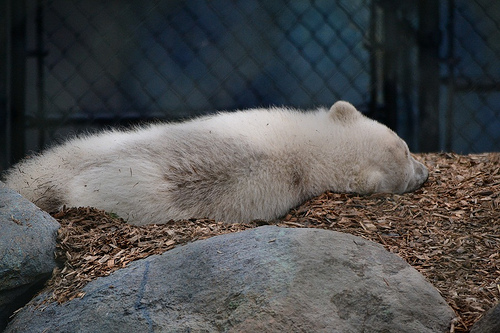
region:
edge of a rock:
[368, 255, 387, 280]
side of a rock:
[173, 287, 185, 294]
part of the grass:
[456, 231, 476, 257]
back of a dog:
[131, 135, 166, 186]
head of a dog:
[386, 148, 391, 158]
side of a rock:
[56, 250, 62, 260]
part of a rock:
[188, 278, 201, 291]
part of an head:
[374, 153, 393, 174]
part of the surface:
[444, 193, 456, 215]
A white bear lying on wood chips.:
[0, 100, 488, 227]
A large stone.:
[5, 225, 460, 330]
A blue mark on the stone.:
[121, 257, 161, 327]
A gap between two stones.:
[3, 275, 55, 326]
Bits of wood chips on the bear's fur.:
[7, 116, 328, 211]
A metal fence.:
[5, 15, 495, 155]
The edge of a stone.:
[470, 300, 495, 330]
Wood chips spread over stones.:
[0, 151, 495, 328]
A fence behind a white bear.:
[7, 22, 492, 219]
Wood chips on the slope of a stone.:
[21, 278, 86, 310]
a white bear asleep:
[30, 100, 446, 232]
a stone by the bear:
[35, 220, 470, 327]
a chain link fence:
[50, 13, 404, 122]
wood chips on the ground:
[377, 185, 469, 250]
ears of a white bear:
[309, 100, 394, 199]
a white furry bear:
[49, 103, 429, 223]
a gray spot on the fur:
[139, 125, 251, 211]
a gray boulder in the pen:
[157, 201, 449, 326]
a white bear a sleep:
[60, 91, 460, 236]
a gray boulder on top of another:
[10, 164, 117, 331]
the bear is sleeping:
[101, 92, 447, 229]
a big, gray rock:
[175, 200, 296, 303]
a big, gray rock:
[249, 214, 436, 329]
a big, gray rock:
[73, 219, 419, 329]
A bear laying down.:
[8, 102, 428, 224]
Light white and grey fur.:
[187, 130, 304, 200]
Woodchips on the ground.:
[443, 208, 488, 282]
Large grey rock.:
[133, 224, 455, 331]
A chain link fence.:
[53, 4, 293, 99]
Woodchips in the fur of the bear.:
[125, 165, 140, 190]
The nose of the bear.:
[411, 160, 428, 191]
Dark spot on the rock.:
[331, 285, 391, 332]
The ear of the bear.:
[329, 99, 357, 126]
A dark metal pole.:
[416, 5, 443, 155]